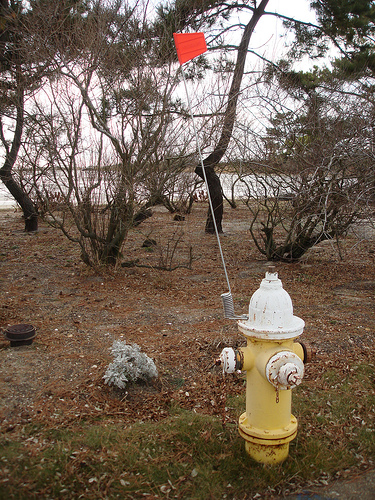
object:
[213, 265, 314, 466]
hydrant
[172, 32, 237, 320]
flag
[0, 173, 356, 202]
lake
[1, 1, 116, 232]
trees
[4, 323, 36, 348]
pipe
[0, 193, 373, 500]
ground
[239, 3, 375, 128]
sky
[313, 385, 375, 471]
grass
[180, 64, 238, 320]
pole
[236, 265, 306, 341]
top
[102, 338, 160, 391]
bush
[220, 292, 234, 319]
coil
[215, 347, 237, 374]
cap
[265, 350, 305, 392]
cap